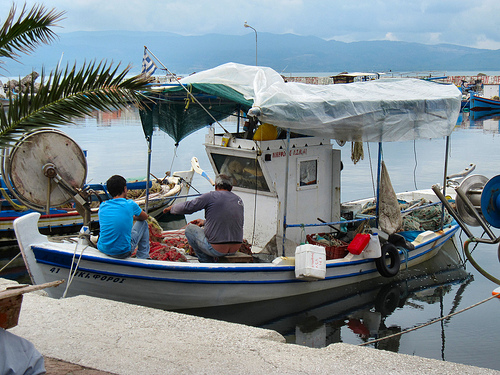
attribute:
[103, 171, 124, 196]
hair — black, man's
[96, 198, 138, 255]
shirt — blue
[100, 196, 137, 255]
shirt — light blue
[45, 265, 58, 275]
number — 4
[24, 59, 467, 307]
boat — blue and white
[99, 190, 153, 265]
shirt — long sleeve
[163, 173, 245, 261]
man — bare skin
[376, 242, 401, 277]
tire — small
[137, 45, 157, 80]
flag — small, blue, white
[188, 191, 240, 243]
shirt — long sleeve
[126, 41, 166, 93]
flag — blue and white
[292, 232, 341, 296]
can — Jerry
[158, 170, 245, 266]
man — sitting, wearing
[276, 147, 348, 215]
window — small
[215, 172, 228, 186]
cap — white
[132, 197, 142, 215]
sleeve — short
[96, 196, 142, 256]
shirt — blue